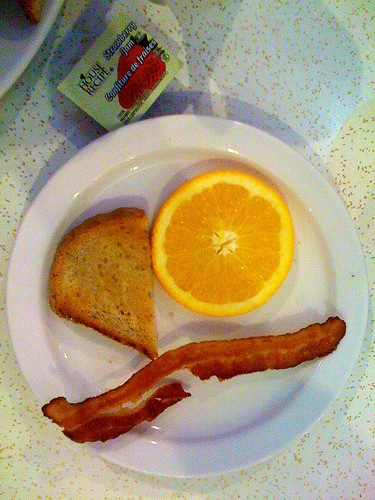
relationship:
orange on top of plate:
[145, 161, 316, 328] [8, 121, 366, 495]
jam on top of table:
[56, 16, 190, 136] [192, 1, 374, 103]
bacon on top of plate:
[45, 319, 355, 458] [8, 121, 366, 495]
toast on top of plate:
[49, 205, 152, 365] [8, 121, 366, 495]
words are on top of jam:
[75, 61, 116, 98] [56, 16, 190, 136]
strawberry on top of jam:
[108, 41, 164, 110] [56, 16, 190, 136]